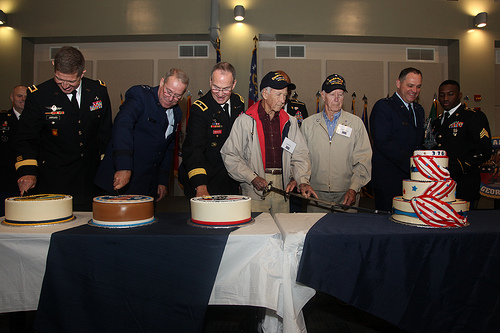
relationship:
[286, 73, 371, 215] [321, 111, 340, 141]
man wearing shirt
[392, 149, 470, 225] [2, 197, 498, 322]
cake on table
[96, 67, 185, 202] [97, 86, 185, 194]
man wearing jacket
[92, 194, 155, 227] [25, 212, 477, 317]
cake on table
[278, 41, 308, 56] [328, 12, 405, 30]
vent on wall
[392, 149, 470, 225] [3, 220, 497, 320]
cake on table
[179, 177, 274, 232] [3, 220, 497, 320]
cake on table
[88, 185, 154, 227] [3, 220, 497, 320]
cake on table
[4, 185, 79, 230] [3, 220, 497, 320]
cake on table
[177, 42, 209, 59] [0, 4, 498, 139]
vent on wall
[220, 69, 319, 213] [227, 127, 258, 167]
man wearing jacket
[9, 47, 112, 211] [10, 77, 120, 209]
man in uniform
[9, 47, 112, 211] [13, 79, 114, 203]
man in uniform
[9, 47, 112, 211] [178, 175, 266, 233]
man cutting cake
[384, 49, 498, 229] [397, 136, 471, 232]
two men standing in front of cake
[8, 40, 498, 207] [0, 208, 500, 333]
men in front of men tables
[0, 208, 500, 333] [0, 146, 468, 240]
men tables full of cakes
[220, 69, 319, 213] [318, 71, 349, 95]
man wearing ball cap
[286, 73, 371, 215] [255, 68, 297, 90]
man wearing ball cap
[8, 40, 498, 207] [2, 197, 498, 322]
men in front of table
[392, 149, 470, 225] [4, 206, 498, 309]
cake on table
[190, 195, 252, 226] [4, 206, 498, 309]
cake on table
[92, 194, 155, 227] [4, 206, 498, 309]
cake on table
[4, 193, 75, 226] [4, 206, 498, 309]
cake on table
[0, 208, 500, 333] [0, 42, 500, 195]
men tables in front of men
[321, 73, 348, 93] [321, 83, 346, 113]
ball cap on head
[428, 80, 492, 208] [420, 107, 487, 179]
man wearing military uniform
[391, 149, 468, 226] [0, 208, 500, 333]
cake on men tables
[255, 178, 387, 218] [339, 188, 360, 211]
sword in hand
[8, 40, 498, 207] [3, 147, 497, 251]
men standing behind cakes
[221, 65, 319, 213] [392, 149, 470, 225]
man cutting cake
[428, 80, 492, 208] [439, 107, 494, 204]
man in uniform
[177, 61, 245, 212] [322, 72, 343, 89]
man in uniform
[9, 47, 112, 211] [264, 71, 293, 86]
man in uniform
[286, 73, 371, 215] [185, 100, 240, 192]
man in uniform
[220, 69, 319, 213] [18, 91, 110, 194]
man in uniform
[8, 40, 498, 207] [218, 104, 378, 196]
men wearing jackets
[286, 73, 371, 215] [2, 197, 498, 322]
man standing at table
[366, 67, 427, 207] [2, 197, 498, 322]
man standing at table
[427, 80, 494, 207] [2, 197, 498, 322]
man standing at table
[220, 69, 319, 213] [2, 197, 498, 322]
man standing at table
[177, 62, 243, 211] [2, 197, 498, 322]
man standing at table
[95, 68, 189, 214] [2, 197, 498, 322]
man standing at table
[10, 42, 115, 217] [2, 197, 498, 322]
man standing at table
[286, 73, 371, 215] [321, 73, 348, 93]
man has ball cap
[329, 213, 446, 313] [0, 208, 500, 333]
cover on men tables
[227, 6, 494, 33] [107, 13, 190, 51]
lights on ceiling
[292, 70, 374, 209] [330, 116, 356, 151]
man has white name tag